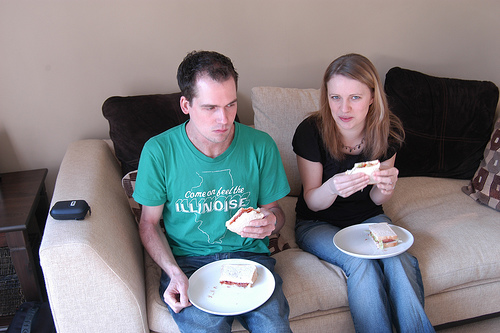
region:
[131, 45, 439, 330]
a couple eating sanwiches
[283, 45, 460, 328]
a woman wearing a black top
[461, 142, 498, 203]
a brown and tan pillow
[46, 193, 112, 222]
a black cell phone case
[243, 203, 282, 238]
a hand holding a half sandwich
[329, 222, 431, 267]
a half sandwich on a white plate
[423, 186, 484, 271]
a cream colored sofa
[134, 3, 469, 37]
a white wall behind the sofa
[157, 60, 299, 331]
an angry man wearing a green t-shirt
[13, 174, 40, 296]
a small wooden chest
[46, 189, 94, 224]
black cell phone on beige couch arm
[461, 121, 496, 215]
dark brown and beige throw pillow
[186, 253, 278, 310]
half of a sandwich on a white plate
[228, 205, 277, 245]
half eaten sandwich being held by hand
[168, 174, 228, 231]
green t-shirt representing a state and poking fun at the name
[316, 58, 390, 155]
woman with blue eyes, red lips, blonde hair wearing a cute necklace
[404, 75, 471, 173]
dark chocolate brown soft throw pillow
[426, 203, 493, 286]
light beige soft sofa cushion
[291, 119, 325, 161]
black short sleeve on t-shirt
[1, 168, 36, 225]
top of brown wood side table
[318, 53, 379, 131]
the head of a woman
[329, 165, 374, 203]
the hand of a woman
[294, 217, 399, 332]
the leg of a woman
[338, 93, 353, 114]
the nose of a woman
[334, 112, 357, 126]
the mouth of a woman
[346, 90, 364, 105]
the eye of a woman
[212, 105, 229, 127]
the nose of a man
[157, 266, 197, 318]
the hand of a man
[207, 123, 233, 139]
the mouth of a man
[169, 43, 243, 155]
the head of a man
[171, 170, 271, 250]
Green tshirt with an outline of Illinois.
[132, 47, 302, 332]
Man sitting on a couch.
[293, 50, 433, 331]
Woman sitting on the couch.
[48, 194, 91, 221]
Phone sitting on the edge of the couch.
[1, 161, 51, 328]
End table next to couch.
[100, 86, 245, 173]
Dark pillow behind the man.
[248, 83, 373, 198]
Light colored pillow behind the woman.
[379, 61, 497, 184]
Dark pillow to the side of the woman.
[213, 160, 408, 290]
Sandwiches on a plate.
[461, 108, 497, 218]
Colored pillow on the couch.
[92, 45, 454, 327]
two people sitting on a couch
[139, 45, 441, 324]
a man and a woman eating on a couch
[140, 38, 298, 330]
a man eating a sandwich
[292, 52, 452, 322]
a blonde woman eating a sandwich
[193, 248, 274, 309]
a sandwich on a white plate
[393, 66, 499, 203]
two cushions on a couch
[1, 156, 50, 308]
a small wooden table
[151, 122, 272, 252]
a man wearing a turquoise T-shirt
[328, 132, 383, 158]
a woman wearing a necklace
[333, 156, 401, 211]
a woman holding a sandwich